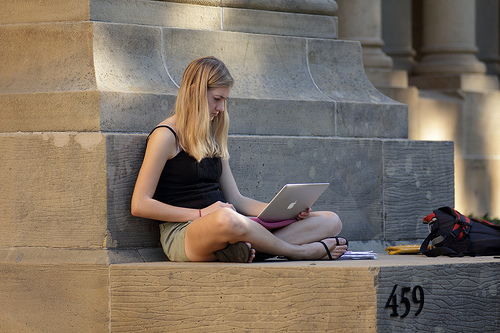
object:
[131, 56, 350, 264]
person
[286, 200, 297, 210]
apple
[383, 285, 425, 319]
number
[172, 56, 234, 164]
hair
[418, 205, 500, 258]
backpack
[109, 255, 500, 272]
floor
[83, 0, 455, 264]
wall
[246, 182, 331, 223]
computer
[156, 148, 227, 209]
top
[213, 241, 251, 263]
flip flop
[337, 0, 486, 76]
column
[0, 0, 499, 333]
background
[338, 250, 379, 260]
envelope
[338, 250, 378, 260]
paper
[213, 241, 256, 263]
foot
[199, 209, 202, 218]
band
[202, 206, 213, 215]
wrist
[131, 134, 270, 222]
arm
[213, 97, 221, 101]
eye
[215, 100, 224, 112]
nose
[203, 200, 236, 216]
hand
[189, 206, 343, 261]
leg